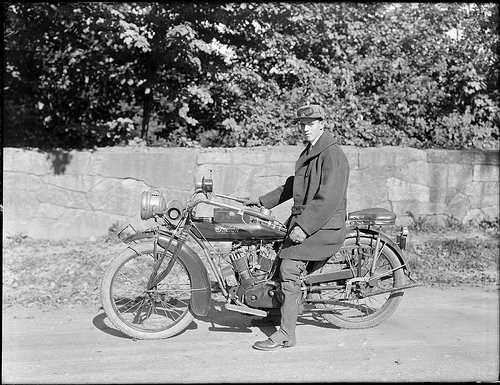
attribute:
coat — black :
[256, 133, 354, 263]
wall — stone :
[4, 150, 490, 243]